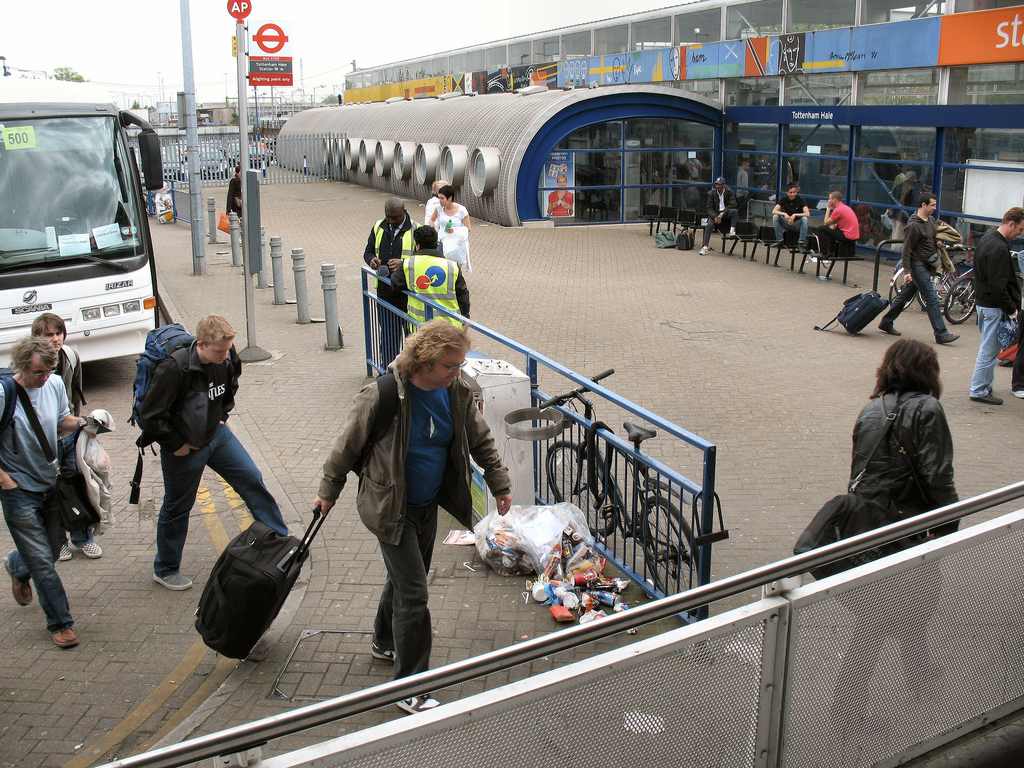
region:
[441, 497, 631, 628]
a plastic trash bag with spilled trash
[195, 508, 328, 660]
a black colored suitcase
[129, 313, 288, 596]
a person wearing a black shirt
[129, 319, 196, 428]
a blue colored backpack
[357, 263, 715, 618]
a silver colored metal fence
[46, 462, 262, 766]
double yellow lines at the curb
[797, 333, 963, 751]
woman in black carrying suitcase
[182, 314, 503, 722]
man in jacket pulling black suitcase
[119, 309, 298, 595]
man in black jacket wearing blue suitcase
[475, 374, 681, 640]
torn trash bag by fence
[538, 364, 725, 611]
black bike leaned up against rail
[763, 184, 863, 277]
two men sitting and talking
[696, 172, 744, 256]
man in black jacket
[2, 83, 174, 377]
white bus with number 500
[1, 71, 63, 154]
white bus with number 500 in yellow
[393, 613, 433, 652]
leg of the person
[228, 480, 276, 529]
leg of the person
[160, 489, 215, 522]
leg of the person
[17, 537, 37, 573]
leg of the person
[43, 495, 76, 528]
leg of the person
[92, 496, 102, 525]
leg of the person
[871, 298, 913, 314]
leg of the person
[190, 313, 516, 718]
man pulling a black suitcase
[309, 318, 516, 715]
man wearing a brown coat and blue shirt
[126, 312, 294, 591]
man carrying a blue backpack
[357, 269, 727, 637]
bicycle parked next to blue fence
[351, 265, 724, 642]
trash bag next to blue fence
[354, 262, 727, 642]
spilled trash next to blue fence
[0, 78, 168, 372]
white bus is parked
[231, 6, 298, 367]
white and red sign hanging on gray pole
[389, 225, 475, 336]
person wearing yellow safety vest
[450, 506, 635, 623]
bag of spilled garbage on ground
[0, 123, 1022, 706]
a group of people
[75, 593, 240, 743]
yellow line on the ground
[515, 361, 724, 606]
bike on a rack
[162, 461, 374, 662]
a black rolling suitcase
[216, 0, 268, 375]
sign on a pole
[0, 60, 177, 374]
truck on the side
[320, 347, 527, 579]
woman wearing a brown jacket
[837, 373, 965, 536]
a black leather jacket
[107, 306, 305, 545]
boy with a backpack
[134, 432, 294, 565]
the mans legs below torso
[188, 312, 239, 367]
the mans head above shoulders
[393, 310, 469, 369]
the hair on the mans head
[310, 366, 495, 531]
the mans shirt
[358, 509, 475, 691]
the mans pants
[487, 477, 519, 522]
the mans hand at end of arm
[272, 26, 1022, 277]
building on the side of the road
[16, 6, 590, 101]
the sky above the buildings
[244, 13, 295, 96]
a sign on the structure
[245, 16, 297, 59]
the top of the sign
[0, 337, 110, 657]
A person walking on a street.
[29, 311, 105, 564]
A person walking on a street.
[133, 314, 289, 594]
A person walking on a street.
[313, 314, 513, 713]
A person walking on a sidewalk.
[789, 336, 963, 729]
A person walking on a sidewalk.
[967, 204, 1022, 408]
A person is standing up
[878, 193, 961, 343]
A person walking on a street.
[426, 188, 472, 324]
A person is standing up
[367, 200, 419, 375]
A person is standing up